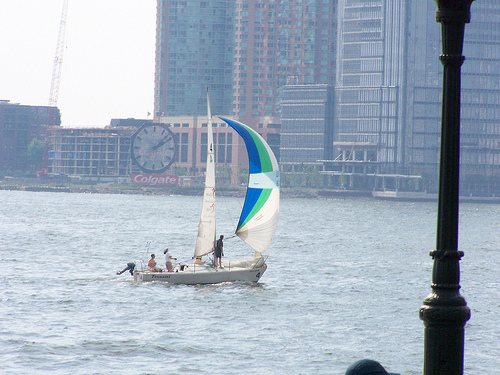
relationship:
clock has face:
[127, 124, 179, 174] [135, 129, 174, 166]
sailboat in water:
[122, 99, 279, 287] [0, 187, 500, 372]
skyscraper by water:
[336, 4, 497, 171] [0, 187, 500, 372]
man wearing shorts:
[208, 232, 226, 268] [213, 253, 228, 264]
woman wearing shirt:
[162, 243, 177, 270] [165, 255, 172, 263]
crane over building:
[47, 3, 71, 111] [4, 104, 60, 171]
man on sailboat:
[208, 232, 226, 268] [122, 99, 279, 287]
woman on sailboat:
[162, 243, 177, 270] [122, 99, 279, 287]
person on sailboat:
[147, 252, 160, 272] [122, 99, 279, 287]